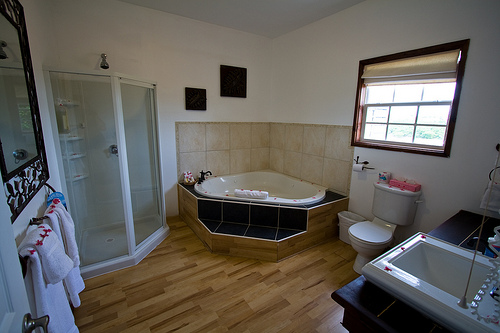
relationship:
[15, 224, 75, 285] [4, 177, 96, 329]
towel on rack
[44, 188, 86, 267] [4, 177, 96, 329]
towel on rack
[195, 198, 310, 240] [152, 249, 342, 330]
tile on floor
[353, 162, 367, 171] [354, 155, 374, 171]
toilet paper on holder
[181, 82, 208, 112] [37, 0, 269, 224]
pictures hanging on wall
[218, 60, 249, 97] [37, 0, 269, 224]
pictures hanging on wall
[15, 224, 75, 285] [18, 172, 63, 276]
towel hanging on rack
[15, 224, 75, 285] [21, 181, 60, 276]
towel hanging from rack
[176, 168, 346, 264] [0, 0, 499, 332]
bathtub in bathroom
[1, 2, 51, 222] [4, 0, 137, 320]
mirror on wall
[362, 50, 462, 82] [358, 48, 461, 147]
blinds on window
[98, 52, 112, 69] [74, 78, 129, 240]
shower head on wall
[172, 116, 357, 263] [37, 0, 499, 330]
bathtub in bathroom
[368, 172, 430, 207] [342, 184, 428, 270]
pink objects are on toilet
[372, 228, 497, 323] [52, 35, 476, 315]
white sink in bathroom